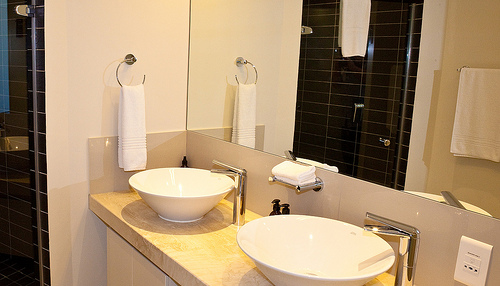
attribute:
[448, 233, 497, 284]
switch — white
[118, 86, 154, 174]
cloth — white 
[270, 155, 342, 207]
soap — white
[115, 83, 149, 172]
towel — white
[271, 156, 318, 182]
towels — small, white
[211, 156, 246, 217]
faucet — silver 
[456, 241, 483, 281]
outlet — white, electrical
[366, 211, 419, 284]
faucet — silver 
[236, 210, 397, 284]
sink — white 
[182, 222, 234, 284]
counter — yellow 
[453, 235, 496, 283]
outlet — electric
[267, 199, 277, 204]
top — black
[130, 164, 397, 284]
sinks — white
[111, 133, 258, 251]
bowl — white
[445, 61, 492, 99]
towel — hanging, white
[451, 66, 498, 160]
towel — white 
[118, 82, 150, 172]
towel — white, hand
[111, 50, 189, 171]
towel — white 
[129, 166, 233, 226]
bowl — white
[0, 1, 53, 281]
tiles — black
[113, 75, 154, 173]
towels — small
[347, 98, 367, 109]
hinge — silver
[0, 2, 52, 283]
shower — dark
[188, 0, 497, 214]
mirror — clear